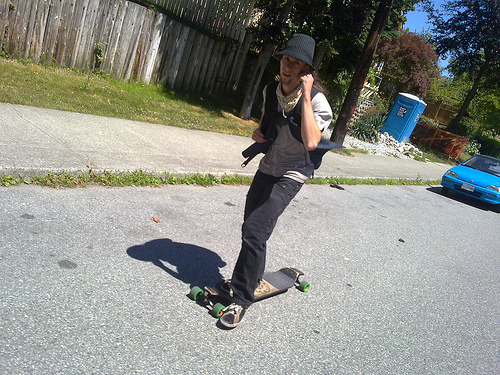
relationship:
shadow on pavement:
[128, 238, 226, 286] [0, 186, 498, 374]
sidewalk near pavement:
[2, 98, 456, 182] [0, 186, 497, 375]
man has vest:
[214, 29, 333, 337] [259, 80, 321, 176]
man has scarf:
[214, 29, 333, 337] [275, 81, 305, 112]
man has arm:
[214, 29, 333, 337] [301, 72, 332, 150]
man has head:
[214, 29, 333, 337] [278, 33, 315, 86]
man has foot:
[214, 29, 333, 337] [219, 290, 254, 329]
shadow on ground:
[128, 238, 226, 286] [10, 179, 442, 373]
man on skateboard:
[214, 29, 333, 337] [185, 265, 315, 323]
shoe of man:
[219, 297, 247, 328] [214, 29, 333, 337]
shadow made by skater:
[128, 238, 226, 286] [215, 32, 338, 334]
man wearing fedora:
[214, 29, 333, 337] [274, 33, 324, 66]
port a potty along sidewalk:
[379, 91, 426, 142] [2, 98, 456, 182]